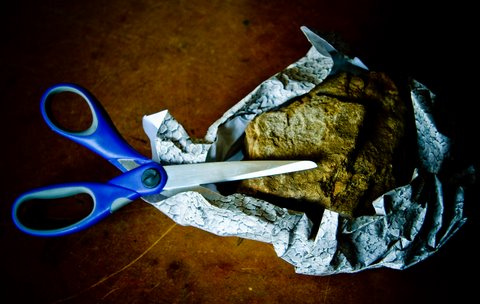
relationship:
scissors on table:
[12, 86, 318, 238] [1, 0, 479, 302]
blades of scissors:
[162, 158, 318, 188] [12, 86, 318, 238]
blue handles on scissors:
[10, 75, 168, 239] [12, 86, 318, 238]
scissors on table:
[12, 86, 318, 238] [13, 33, 446, 282]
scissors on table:
[12, 86, 318, 238] [18, 6, 456, 280]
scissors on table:
[3, 110, 269, 212] [23, 22, 454, 293]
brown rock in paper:
[240, 63, 406, 220] [133, 22, 476, 277]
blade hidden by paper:
[141, 192, 169, 200] [133, 22, 476, 277]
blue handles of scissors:
[10, 84, 168, 239] [12, 86, 318, 238]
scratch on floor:
[78, 221, 196, 293] [0, 0, 480, 304]